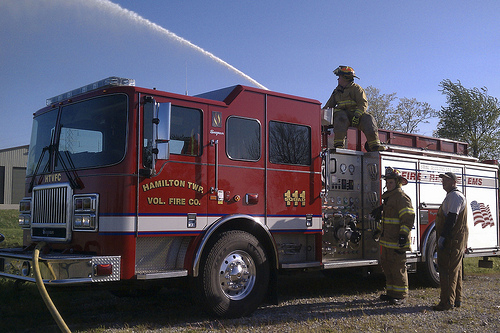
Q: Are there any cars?
A: No, there are no cars.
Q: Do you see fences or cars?
A: No, there are no cars or fences.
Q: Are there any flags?
A: Yes, there is a flag.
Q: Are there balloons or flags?
A: Yes, there is a flag.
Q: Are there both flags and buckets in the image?
A: No, there is a flag but no buckets.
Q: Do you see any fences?
A: No, there are no fences.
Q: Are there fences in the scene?
A: No, there are no fences.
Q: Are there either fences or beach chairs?
A: No, there are no fences or beach chairs.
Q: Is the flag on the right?
A: Yes, the flag is on the right of the image.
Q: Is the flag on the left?
A: No, the flag is on the right of the image.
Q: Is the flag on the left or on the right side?
A: The flag is on the right of the image.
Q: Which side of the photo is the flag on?
A: The flag is on the right of the image.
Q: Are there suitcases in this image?
A: No, there are no suitcases.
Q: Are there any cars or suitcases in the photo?
A: No, there are no suitcases or cars.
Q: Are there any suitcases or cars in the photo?
A: No, there are no suitcases or cars.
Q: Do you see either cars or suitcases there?
A: No, there are no suitcases or cars.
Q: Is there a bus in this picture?
A: No, there are no buses.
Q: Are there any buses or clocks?
A: No, there are no buses or clocks.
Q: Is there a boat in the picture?
A: No, there are no boats.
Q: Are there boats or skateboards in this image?
A: No, there are no boats or skateboards.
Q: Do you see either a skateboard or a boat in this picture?
A: No, there are no boats or skateboards.